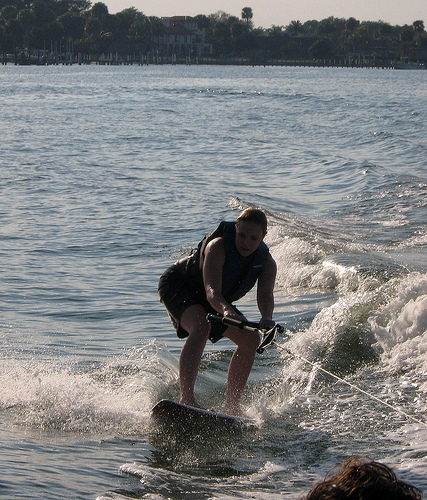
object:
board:
[149, 395, 257, 425]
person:
[156, 206, 279, 414]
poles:
[1, 39, 408, 66]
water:
[0, 60, 425, 500]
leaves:
[1, 1, 427, 71]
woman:
[158, 202, 279, 425]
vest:
[173, 219, 272, 307]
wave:
[194, 210, 424, 462]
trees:
[0, 0, 426, 60]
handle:
[206, 313, 286, 335]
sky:
[87, 0, 425, 27]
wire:
[273, 341, 427, 429]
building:
[141, 15, 216, 60]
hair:
[235, 205, 268, 234]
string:
[273, 340, 426, 435]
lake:
[0, 59, 427, 500]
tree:
[358, 15, 409, 64]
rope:
[273, 340, 427, 430]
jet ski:
[151, 391, 257, 433]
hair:
[236, 206, 271, 230]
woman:
[159, 206, 280, 420]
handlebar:
[203, 311, 286, 357]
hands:
[223, 310, 284, 328]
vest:
[172, 219, 278, 306]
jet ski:
[148, 313, 418, 460]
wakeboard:
[150, 397, 256, 430]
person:
[156, 206, 277, 421]